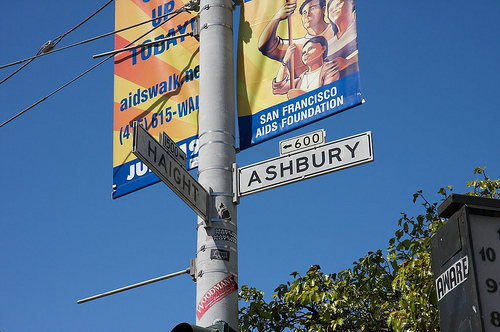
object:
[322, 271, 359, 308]
leaves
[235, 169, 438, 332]
tree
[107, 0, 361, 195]
aids walk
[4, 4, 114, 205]
air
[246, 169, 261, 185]
letter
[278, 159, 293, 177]
h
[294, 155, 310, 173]
b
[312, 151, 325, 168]
u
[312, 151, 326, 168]
sign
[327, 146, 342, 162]
r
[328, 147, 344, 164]
sign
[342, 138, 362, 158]
y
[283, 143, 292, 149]
arrow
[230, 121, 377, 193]
sign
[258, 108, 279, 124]
san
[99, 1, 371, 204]
sign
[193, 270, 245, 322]
sticher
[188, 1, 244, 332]
pole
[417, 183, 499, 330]
corner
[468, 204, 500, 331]
clock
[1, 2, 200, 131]
cables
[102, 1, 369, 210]
banner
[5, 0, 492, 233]
sky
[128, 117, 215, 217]
sign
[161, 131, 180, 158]
numbers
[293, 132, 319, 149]
numbers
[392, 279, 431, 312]
leaves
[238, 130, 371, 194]
ashbury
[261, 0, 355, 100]
image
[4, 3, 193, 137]
wiring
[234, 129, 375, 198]
signs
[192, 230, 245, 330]
sign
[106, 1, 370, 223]
flag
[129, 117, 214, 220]
flag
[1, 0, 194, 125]
lines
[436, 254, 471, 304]
sticker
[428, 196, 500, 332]
box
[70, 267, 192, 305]
pole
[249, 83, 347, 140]
text